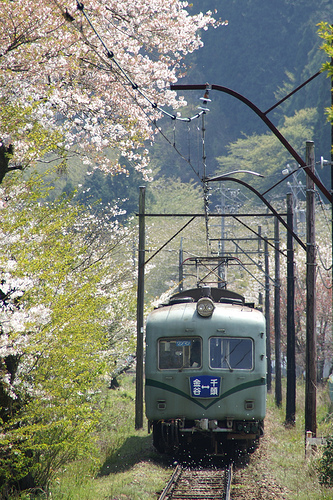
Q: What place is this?
A: It is a field.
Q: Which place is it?
A: It is a field.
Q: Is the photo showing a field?
A: Yes, it is showing a field.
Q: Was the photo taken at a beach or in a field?
A: It was taken at a field.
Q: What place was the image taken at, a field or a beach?
A: It was taken at a field.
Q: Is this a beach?
A: No, it is a field.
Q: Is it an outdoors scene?
A: Yes, it is outdoors.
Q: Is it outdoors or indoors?
A: It is outdoors.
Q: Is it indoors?
A: No, it is outdoors.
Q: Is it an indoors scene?
A: No, it is outdoors.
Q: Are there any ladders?
A: No, there are no ladders.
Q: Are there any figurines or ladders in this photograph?
A: No, there are no ladders or figurines.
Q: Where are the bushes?
A: The bushes are in the field.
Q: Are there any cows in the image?
A: No, there are no cows.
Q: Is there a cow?
A: No, there are no cows.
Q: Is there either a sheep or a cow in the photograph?
A: No, there are no cows or sheep.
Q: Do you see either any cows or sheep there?
A: No, there are no cows or sheep.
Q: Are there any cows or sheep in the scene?
A: No, there are no cows or sheep.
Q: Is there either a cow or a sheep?
A: No, there are no cows or sheep.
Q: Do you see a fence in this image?
A: No, there are no fences.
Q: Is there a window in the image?
A: Yes, there is a window.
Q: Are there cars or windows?
A: Yes, there is a window.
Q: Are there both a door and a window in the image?
A: No, there is a window but no doors.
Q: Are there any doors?
A: No, there are no doors.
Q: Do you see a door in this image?
A: No, there are no doors.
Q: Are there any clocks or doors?
A: No, there are no doors or clocks.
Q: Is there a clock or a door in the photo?
A: No, there are no doors or clocks.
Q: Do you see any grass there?
A: Yes, there is grass.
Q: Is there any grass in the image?
A: Yes, there is grass.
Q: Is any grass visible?
A: Yes, there is grass.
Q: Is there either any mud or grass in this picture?
A: Yes, there is grass.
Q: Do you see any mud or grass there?
A: Yes, there is grass.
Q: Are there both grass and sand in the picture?
A: No, there is grass but no sand.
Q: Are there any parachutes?
A: No, there are no parachutes.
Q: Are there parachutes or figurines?
A: No, there are no parachutes or figurines.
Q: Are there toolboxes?
A: No, there are no toolboxes.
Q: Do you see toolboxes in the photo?
A: No, there are no toolboxes.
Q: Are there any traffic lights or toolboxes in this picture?
A: No, there are no toolboxes or traffic lights.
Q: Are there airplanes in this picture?
A: No, there are no airplanes.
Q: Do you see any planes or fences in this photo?
A: No, there are no planes or fences.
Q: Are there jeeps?
A: No, there are no jeeps.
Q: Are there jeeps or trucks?
A: No, there are no jeeps or trucks.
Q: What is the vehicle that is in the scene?
A: The vehicle is a car.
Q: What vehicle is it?
A: The vehicle is a car.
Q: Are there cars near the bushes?
A: Yes, there is a car near the bushes.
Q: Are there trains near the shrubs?
A: No, there is a car near the shrubs.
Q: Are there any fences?
A: No, there are no fences.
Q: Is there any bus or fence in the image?
A: No, there are no fences or buses.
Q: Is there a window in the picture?
A: Yes, there is a window.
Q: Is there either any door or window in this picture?
A: Yes, there is a window.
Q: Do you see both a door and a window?
A: No, there is a window but no doors.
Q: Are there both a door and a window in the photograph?
A: No, there is a window but no doors.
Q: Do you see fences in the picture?
A: No, there are no fences.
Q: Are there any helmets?
A: No, there are no helmets.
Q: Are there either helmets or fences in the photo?
A: No, there are no helmets or fences.